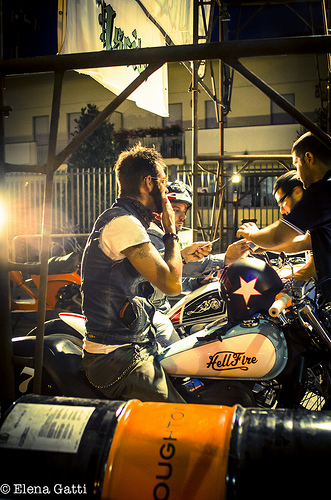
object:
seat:
[10, 331, 81, 374]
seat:
[20, 251, 81, 276]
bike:
[9, 282, 331, 411]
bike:
[25, 247, 316, 337]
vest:
[81, 204, 152, 357]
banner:
[57, 0, 170, 118]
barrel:
[1, 392, 331, 498]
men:
[235, 132, 331, 304]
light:
[229, 170, 242, 184]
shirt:
[78, 211, 153, 355]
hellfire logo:
[206, 349, 257, 370]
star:
[233, 276, 262, 303]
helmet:
[219, 256, 282, 324]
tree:
[62, 97, 118, 228]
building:
[1, 1, 330, 284]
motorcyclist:
[79, 143, 188, 404]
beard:
[151, 175, 165, 215]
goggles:
[168, 185, 194, 197]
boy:
[79, 145, 213, 402]